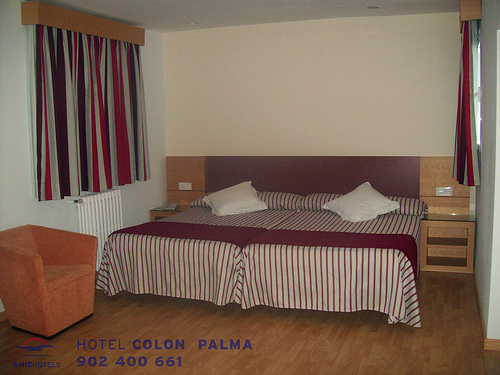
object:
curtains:
[19, 18, 151, 203]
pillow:
[199, 176, 270, 218]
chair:
[0, 222, 101, 339]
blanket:
[97, 218, 430, 262]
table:
[418, 208, 479, 277]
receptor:
[177, 180, 193, 191]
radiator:
[74, 187, 127, 272]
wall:
[0, 0, 175, 229]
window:
[22, 0, 148, 203]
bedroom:
[0, 0, 500, 373]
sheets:
[95, 183, 431, 335]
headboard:
[162, 155, 478, 208]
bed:
[94, 151, 440, 331]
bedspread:
[97, 147, 436, 332]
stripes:
[96, 187, 428, 328]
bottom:
[92, 235, 240, 307]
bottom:
[231, 223, 429, 319]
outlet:
[431, 183, 453, 199]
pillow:
[320, 181, 403, 224]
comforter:
[92, 190, 427, 330]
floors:
[0, 271, 500, 375]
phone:
[152, 197, 180, 213]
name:
[75, 334, 254, 352]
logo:
[12, 334, 64, 371]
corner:
[0, 333, 50, 374]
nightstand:
[148, 199, 187, 224]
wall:
[144, 8, 457, 156]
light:
[466, 16, 483, 146]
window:
[451, 1, 491, 193]